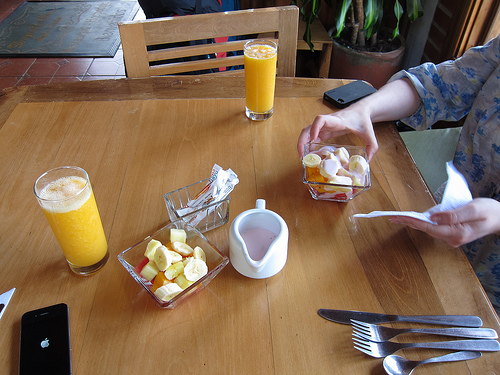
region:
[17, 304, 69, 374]
a black cellphone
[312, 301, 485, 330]
a long butter knife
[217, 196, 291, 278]
a white serving mug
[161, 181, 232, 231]
a small glass dish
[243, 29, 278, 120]
a tall glass of orange juice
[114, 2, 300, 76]
a light brown wooden chair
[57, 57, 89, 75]
a red tile square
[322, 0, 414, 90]
a potted plant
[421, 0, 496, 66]
a wooden section of a door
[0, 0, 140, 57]
a dark area rug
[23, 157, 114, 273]
Glass of orange juice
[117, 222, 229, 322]
Square bowl with chopped fruit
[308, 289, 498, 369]
Four utensils on table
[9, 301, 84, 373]
Iphone on the table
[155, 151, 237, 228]
Glass condiment container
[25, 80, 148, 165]
Brown square wooden table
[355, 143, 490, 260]
Napkin in the woman's hand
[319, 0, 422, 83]
Potted plant in background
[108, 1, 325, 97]
Wooden chair close to table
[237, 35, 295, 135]
Glass of orange juice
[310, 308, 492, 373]
four utensils on table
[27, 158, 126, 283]
orange juice in glass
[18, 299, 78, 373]
black phone on table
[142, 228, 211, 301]
sliced banana in bowl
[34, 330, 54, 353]
white logo on phone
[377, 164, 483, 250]
hand holding white napkin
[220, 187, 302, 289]
coffee creamer on table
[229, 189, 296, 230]
handle on white pitcher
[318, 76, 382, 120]
black phone on table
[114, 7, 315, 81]
back of wood chair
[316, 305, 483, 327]
silver butter knife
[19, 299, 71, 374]
black Apple iPhone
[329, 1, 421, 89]
large potted plant in terra cotta pot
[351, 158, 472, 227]
white napkin in woman's hand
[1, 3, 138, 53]
black mat with gold lettering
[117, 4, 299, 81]
empty wooden chair at the table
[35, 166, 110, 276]
full glass of orange juice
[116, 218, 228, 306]
bowl filled with sliced bananas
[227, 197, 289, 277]
empty white pitcher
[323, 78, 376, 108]
upside down black phone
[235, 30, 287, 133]
glass of orange juice on table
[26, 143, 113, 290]
glass of orange juice on table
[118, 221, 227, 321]
square glass dish with fruit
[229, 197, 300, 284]
white creamer container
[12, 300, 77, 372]
black cell phone sitting on table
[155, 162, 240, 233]
condiments on table in glass container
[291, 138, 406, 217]
square glass dish with fruit in it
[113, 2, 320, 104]
empty wooden straight back chair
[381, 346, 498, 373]
metal spoon on table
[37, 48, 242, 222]
wooden table with food on it